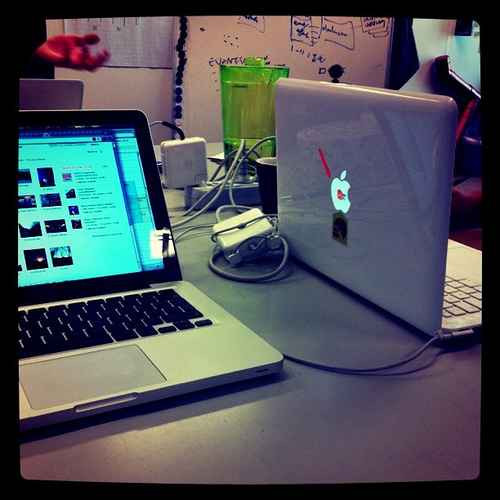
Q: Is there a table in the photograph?
A: Yes, there is a table.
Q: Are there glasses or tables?
A: Yes, there is a table.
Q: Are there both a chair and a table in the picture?
A: No, there is a table but no chairs.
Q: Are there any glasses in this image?
A: No, there are no glasses.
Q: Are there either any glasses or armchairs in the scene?
A: No, there are no glasses or armchairs.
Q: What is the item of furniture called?
A: The piece of furniture is a table.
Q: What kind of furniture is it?
A: The piece of furniture is a table.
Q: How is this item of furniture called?
A: This is a table.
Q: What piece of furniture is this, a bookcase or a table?
A: This is a table.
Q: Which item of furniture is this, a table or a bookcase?
A: This is a table.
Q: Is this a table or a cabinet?
A: This is a table.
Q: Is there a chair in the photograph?
A: No, there are no chairs.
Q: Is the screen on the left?
A: Yes, the screen is on the left of the image.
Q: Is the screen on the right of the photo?
A: No, the screen is on the left of the image.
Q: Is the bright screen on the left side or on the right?
A: The screen is on the left of the image.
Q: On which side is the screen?
A: The screen is on the left of the image.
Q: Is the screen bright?
A: Yes, the screen is bright.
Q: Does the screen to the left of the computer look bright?
A: Yes, the screen is bright.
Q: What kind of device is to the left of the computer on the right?
A: The device is a screen.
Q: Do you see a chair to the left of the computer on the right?
A: No, there is a screen to the left of the computer.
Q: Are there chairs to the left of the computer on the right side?
A: No, there is a screen to the left of the computer.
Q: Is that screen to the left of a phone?
A: No, the screen is to the left of the computer.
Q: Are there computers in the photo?
A: Yes, there is a computer.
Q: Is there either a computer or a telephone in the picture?
A: Yes, there is a computer.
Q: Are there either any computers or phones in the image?
A: Yes, there is a computer.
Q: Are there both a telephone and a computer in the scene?
A: No, there is a computer but no phones.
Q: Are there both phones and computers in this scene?
A: No, there is a computer but no phones.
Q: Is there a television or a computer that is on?
A: Yes, the computer is on.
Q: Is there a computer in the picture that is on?
A: Yes, there is a computer that is on.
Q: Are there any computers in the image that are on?
A: Yes, there is a computer that is on.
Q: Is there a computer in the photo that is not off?
A: Yes, there is a computer that is on.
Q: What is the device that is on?
A: The device is a computer.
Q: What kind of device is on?
A: The device is a computer.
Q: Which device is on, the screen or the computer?
A: The computer is on.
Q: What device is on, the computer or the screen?
A: The computer is on.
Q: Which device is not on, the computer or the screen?
A: The screen is not on.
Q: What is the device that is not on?
A: The device is a screen.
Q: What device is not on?
A: The device is a screen.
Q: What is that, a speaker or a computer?
A: That is a computer.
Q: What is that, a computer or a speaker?
A: That is a computer.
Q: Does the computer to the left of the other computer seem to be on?
A: Yes, the computer is on.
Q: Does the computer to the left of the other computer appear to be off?
A: No, the computer is on.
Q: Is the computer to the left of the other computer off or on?
A: The computer is on.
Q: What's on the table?
A: The computer is on the table.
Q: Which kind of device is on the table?
A: The device is a computer.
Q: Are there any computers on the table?
A: Yes, there is a computer on the table.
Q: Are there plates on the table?
A: No, there is a computer on the table.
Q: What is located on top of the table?
A: The computer is on top of the table.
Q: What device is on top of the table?
A: The device is a computer.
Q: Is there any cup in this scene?
A: Yes, there is a cup.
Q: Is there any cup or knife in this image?
A: Yes, there is a cup.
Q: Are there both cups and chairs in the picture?
A: No, there is a cup but no chairs.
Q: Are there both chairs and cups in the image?
A: No, there is a cup but no chairs.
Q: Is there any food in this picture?
A: No, there is no food.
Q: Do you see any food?
A: No, there is no food.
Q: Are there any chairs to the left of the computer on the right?
A: No, there is a cup to the left of the computer.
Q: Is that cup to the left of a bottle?
A: No, the cup is to the left of a computer.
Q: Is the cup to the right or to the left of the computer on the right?
A: The cup is to the left of the computer.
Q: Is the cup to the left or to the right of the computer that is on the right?
A: The cup is to the left of the computer.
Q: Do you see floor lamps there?
A: No, there are no floor lamps.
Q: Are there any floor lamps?
A: No, there are no floor lamps.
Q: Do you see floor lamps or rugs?
A: No, there are no floor lamps or rugs.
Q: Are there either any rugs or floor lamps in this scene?
A: No, there are no floor lamps or rugs.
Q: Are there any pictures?
A: No, there are no pictures.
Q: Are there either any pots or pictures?
A: No, there are no pictures or pots.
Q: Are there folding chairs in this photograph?
A: No, there are no folding chairs.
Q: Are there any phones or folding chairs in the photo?
A: No, there are no folding chairs or phones.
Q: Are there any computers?
A: Yes, there is a computer.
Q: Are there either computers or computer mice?
A: Yes, there is a computer.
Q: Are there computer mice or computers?
A: Yes, there is a computer.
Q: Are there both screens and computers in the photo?
A: Yes, there are both a computer and a screen.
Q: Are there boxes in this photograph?
A: No, there are no boxes.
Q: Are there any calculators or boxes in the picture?
A: No, there are no boxes or calculators.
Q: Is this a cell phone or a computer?
A: This is a computer.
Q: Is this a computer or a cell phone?
A: This is a computer.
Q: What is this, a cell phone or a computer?
A: This is a computer.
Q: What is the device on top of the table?
A: The device is a computer.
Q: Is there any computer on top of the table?
A: Yes, there is a computer on top of the table.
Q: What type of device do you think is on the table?
A: The device is a computer.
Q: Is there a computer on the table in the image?
A: Yes, there is a computer on the table.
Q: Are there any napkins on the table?
A: No, there is a computer on the table.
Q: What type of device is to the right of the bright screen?
A: The device is a computer.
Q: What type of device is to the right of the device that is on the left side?
A: The device is a computer.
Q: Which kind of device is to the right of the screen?
A: The device is a computer.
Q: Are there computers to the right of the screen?
A: Yes, there is a computer to the right of the screen.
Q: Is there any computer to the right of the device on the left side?
A: Yes, there is a computer to the right of the screen.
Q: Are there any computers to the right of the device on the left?
A: Yes, there is a computer to the right of the screen.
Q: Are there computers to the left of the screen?
A: No, the computer is to the right of the screen.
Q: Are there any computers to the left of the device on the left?
A: No, the computer is to the right of the screen.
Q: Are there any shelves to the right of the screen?
A: No, there is a computer to the right of the screen.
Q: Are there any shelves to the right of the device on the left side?
A: No, there is a computer to the right of the screen.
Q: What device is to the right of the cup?
A: The device is a computer.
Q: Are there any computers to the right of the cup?
A: Yes, there is a computer to the right of the cup.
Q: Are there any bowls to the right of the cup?
A: No, there is a computer to the right of the cup.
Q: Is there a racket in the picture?
A: No, there are no rackets.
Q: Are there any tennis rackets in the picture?
A: No, there are no tennis rackets.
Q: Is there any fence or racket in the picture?
A: No, there are no rackets or fences.